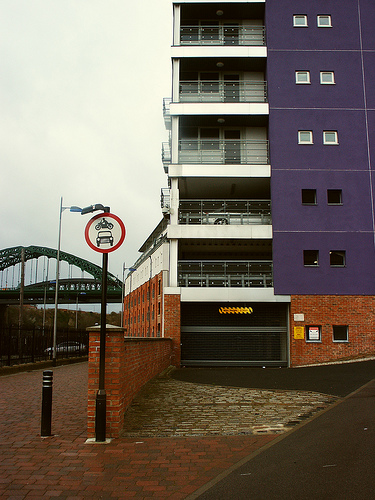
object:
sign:
[85, 214, 126, 253]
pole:
[94, 252, 109, 443]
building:
[123, 5, 372, 363]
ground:
[4, 362, 284, 494]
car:
[45, 342, 87, 359]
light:
[51, 196, 82, 363]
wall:
[85, 327, 174, 444]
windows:
[319, 70, 334, 84]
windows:
[296, 130, 312, 144]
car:
[96, 231, 114, 248]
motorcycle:
[95, 217, 114, 230]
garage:
[0, 325, 87, 373]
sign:
[218, 306, 254, 315]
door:
[180, 331, 281, 364]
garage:
[176, 177, 292, 367]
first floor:
[162, 288, 374, 369]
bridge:
[0, 245, 125, 304]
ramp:
[180, 365, 375, 500]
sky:
[6, 6, 172, 316]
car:
[198, 205, 271, 224]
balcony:
[163, 98, 173, 130]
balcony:
[162, 142, 172, 172]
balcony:
[160, 188, 169, 217]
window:
[293, 16, 309, 28]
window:
[318, 14, 331, 29]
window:
[305, 325, 323, 341]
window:
[333, 325, 347, 342]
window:
[303, 248, 321, 266]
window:
[329, 249, 344, 266]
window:
[303, 188, 317, 204]